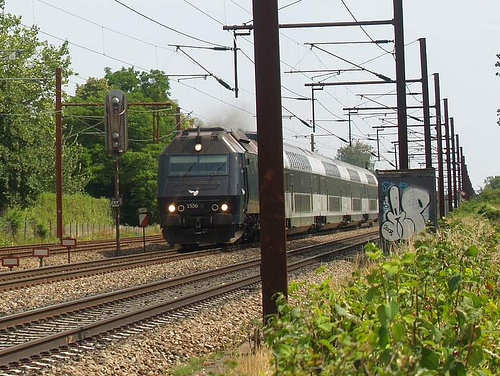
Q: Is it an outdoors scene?
A: Yes, it is outdoors.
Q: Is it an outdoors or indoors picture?
A: It is outdoors.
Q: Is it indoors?
A: No, it is outdoors.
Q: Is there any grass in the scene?
A: Yes, there is grass.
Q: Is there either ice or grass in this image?
A: Yes, there is grass.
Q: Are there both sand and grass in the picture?
A: No, there is grass but no sand.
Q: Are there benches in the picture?
A: No, there are no benches.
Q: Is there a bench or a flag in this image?
A: No, there are no benches or flags.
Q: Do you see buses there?
A: No, there are no buses.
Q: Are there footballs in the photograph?
A: No, there are no footballs.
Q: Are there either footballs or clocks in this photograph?
A: No, there are no footballs or clocks.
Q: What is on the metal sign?
A: The graffiti is on the sign.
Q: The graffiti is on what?
A: The graffiti is on the sign.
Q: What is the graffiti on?
A: The graffiti is on the sign.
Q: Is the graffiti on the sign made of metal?
A: Yes, the graffiti is on the sign.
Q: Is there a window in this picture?
A: Yes, there are windows.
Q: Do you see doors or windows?
A: Yes, there are windows.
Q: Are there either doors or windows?
A: Yes, there are windows.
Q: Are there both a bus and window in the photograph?
A: No, there are windows but no buses.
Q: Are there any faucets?
A: No, there are no faucets.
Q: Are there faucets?
A: No, there are no faucets.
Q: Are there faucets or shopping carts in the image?
A: No, there are no faucets or shopping carts.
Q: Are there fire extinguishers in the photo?
A: No, there are no fire extinguishers.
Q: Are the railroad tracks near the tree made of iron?
A: Yes, the train tracks are made of iron.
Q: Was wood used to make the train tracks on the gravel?
A: No, the train tracks are made of iron.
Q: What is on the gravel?
A: The train tracks are on the gravel.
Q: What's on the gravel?
A: The train tracks are on the gravel.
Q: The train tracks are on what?
A: The train tracks are on the gravel.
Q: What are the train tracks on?
A: The train tracks are on the gravel.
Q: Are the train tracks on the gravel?
A: Yes, the train tracks are on the gravel.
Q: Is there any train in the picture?
A: Yes, there is a train.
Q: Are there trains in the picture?
A: Yes, there is a train.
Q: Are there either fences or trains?
A: Yes, there is a train.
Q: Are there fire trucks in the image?
A: No, there are no fire trucks.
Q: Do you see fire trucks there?
A: No, there are no fire trucks.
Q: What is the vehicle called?
A: The vehicle is a train.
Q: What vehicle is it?
A: The vehicle is a train.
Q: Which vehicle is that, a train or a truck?
A: That is a train.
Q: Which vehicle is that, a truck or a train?
A: That is a train.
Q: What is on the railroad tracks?
A: The train is on the railroad tracks.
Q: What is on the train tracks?
A: The train is on the railroad tracks.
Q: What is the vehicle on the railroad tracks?
A: The vehicle is a train.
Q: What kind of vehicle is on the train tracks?
A: The vehicle is a train.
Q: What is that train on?
A: The train is on the train tracks.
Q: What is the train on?
A: The train is on the train tracks.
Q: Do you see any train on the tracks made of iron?
A: Yes, there is a train on the train tracks.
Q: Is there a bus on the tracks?
A: No, there is a train on the tracks.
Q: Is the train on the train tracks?
A: Yes, the train is on the train tracks.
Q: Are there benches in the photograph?
A: No, there are no benches.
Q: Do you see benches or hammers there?
A: No, there are no benches or hammers.